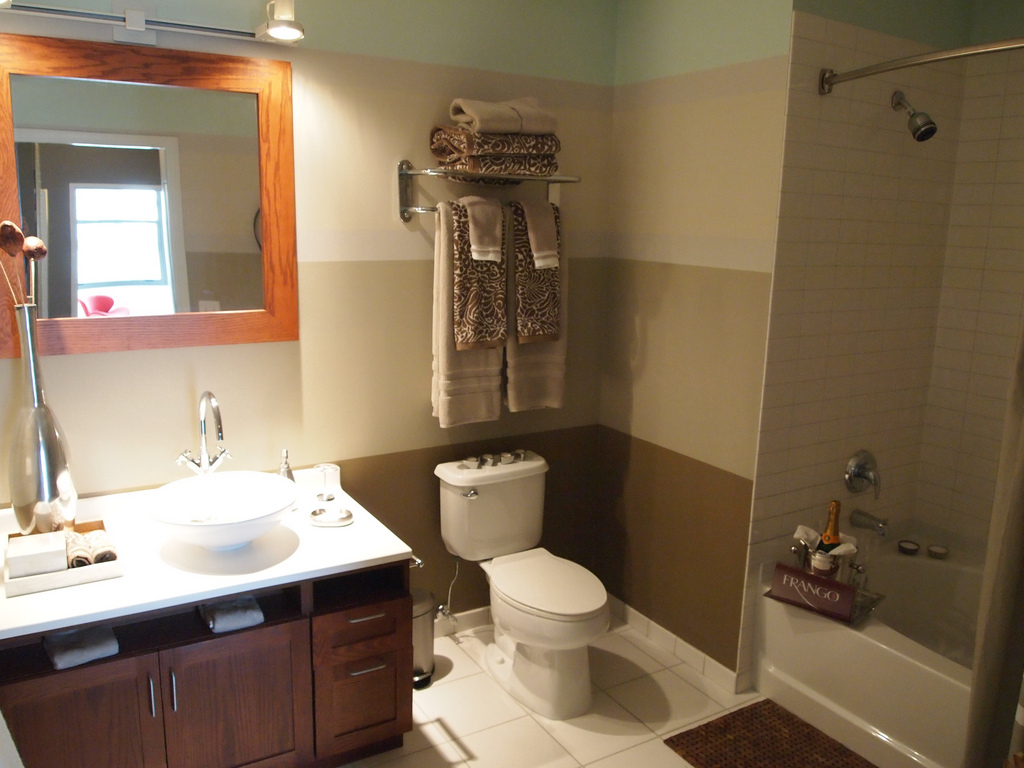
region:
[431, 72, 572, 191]
towels stacked on top of the rack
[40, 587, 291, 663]
hand towels underneath the sink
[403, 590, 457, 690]
small metal trash can by the toilet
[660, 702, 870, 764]
rug on the floor in front of the tub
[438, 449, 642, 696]
white toilet in the bathroom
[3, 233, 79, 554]
tall vase on the top of the counter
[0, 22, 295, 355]
wood framed mirror above the sink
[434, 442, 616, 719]
White toilet against wall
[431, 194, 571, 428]
Towels on towel rack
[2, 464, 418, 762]
Wooden vanity with white countertop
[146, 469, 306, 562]
White basin sink on countertop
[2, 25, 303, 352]
Wall mirror with wooden frame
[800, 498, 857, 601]
Bottle of champagne on side of tub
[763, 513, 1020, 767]
White bathtub in corner of bathroom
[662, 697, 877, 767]
Brown bath rug by bathtub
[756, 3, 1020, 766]
Stand up shower connected to tub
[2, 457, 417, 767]
Wooden vanity with white counter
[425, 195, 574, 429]
Towels hanging on towel rack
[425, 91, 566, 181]
Towels stacked on towel rack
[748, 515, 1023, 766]
Bathtub in corner of bathroom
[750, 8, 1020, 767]
Shower connected to bathtub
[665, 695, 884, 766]
Brown bathroom rug by bathtub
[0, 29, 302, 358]
mirror has wooden frame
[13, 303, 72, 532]
vase on counter is metal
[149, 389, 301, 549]
sink on bathroom counter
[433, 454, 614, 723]
toilet is white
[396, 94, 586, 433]
many towels on the towel rack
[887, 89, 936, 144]
shower head in the shower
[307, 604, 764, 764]
floor is white tile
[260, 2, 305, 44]
light above bathroom mirror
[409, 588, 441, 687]
metal trash can next to toilet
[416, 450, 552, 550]
a tank that is white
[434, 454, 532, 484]
a tank lid that is white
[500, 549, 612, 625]
the lid that is white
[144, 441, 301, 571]
a sink that is white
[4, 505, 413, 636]
a counter that is white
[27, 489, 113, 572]
a towel that is white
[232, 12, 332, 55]
a light that is white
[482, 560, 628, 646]
the toilet seat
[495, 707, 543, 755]
the tile on the floor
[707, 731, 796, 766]
a brown rug